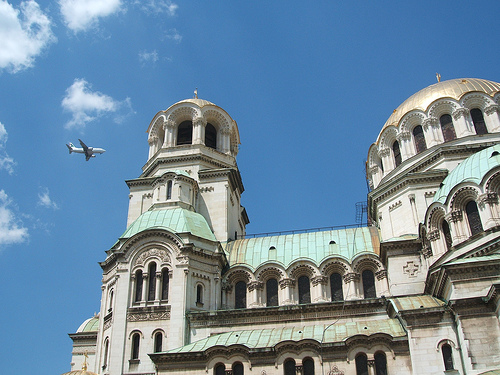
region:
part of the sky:
[275, 46, 330, 98]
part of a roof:
[285, 236, 316, 258]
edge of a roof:
[290, 254, 320, 264]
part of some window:
[133, 273, 165, 301]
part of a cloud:
[67, 1, 98, 43]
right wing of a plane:
[72, 131, 89, 147]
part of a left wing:
[76, 149, 91, 164]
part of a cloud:
[67, 90, 109, 130]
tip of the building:
[180, 80, 210, 104]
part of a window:
[354, 355, 365, 365]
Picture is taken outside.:
[26, 13, 498, 268]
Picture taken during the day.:
[98, 34, 488, 150]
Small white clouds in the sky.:
[15, 11, 145, 145]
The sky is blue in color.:
[187, 12, 454, 99]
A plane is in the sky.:
[48, 94, 115, 222]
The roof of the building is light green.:
[136, 197, 390, 307]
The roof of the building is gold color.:
[364, 56, 497, 133]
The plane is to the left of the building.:
[32, 21, 119, 208]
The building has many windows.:
[78, 71, 486, 363]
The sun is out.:
[22, 21, 479, 100]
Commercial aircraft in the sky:
[51, 114, 138, 204]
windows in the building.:
[103, 223, 223, 348]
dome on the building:
[336, 38, 495, 156]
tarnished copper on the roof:
[146, 205, 479, 316]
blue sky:
[277, 155, 321, 191]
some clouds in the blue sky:
[23, 148, 103, 289]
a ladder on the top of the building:
[356, 190, 377, 245]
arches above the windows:
[222, 256, 413, 316]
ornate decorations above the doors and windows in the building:
[124, 225, 204, 278]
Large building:
[136, 81, 497, 196]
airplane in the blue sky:
[65, 128, 119, 172]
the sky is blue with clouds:
[4, 61, 145, 131]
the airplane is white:
[68, 132, 107, 170]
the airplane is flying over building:
[14, 109, 495, 264]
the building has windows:
[76, 230, 426, 347]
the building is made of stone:
[75, 97, 495, 369]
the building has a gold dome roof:
[333, 55, 498, 112]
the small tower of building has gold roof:
[157, 82, 228, 113]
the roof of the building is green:
[107, 209, 397, 259]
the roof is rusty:
[362, 228, 389, 256]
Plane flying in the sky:
[54, 128, 106, 165]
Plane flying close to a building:
[54, 128, 111, 168]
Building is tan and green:
[54, 77, 496, 372]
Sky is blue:
[1, 7, 498, 102]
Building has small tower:
[116, 79, 256, 241]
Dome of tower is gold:
[362, 70, 498, 122]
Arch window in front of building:
[123, 241, 174, 313]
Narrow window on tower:
[159, 176, 179, 202]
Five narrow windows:
[222, 259, 387, 314]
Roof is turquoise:
[226, 222, 373, 259]